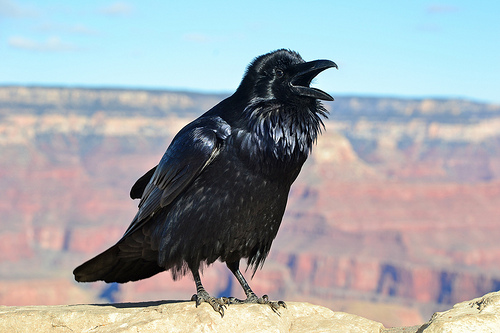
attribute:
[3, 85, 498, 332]
mountain — inside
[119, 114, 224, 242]
wing — black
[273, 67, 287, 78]
eye — black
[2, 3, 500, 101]
sky — clear, blue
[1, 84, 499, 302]
rocks — blurry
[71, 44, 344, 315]
bird — sitting, black, feathered, standing, alone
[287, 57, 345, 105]
beak — open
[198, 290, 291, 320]
claws — sharp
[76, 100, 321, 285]
feathers — glossy